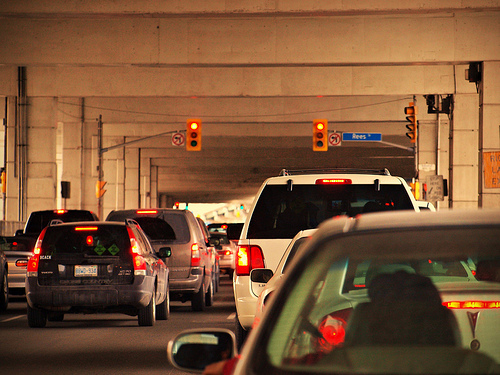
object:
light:
[185, 118, 201, 151]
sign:
[342, 133, 381, 142]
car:
[169, 209, 498, 375]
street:
[102, 345, 124, 354]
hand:
[206, 236, 221, 247]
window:
[247, 184, 414, 238]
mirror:
[166, 327, 237, 374]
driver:
[368, 268, 414, 301]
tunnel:
[13, 0, 497, 205]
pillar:
[2, 121, 64, 234]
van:
[278, 168, 390, 177]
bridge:
[0, 14, 499, 68]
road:
[0, 285, 238, 375]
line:
[0, 314, 26, 322]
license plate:
[73, 265, 98, 277]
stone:
[71, 44, 123, 71]